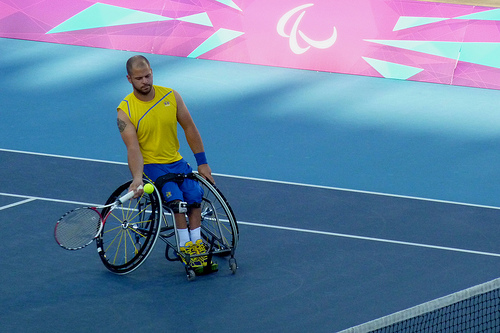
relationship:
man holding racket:
[116, 55, 216, 268] [50, 183, 147, 258]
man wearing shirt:
[116, 55, 216, 268] [113, 88, 188, 161]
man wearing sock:
[116, 55, 216, 268] [190, 224, 203, 246]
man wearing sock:
[116, 55, 216, 268] [172, 227, 193, 251]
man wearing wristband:
[116, 55, 216, 268] [191, 149, 208, 167]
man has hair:
[116, 55, 216, 268] [127, 54, 151, 74]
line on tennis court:
[3, 146, 499, 214] [4, 144, 497, 332]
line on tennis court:
[0, 187, 497, 259] [4, 144, 497, 332]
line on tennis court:
[0, 194, 35, 214] [4, 144, 497, 332]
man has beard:
[116, 55, 216, 268] [131, 83, 154, 97]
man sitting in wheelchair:
[116, 55, 216, 268] [81, 169, 213, 256]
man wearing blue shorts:
[116, 55, 216, 268] [149, 163, 202, 200]